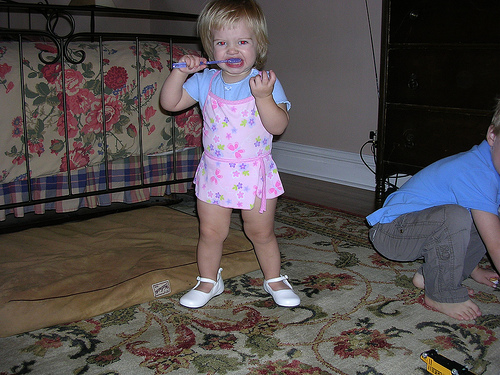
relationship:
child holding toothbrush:
[158, 2, 303, 309] [169, 53, 247, 68]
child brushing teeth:
[158, 2, 303, 309] [226, 58, 242, 66]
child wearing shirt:
[158, 2, 303, 309] [180, 64, 294, 113]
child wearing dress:
[158, 2, 303, 309] [191, 62, 284, 211]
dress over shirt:
[191, 62, 284, 211] [181, 60, 292, 114]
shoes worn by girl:
[148, 258, 409, 367] [156, 0, 323, 309]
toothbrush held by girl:
[172, 58, 243, 69] [156, 0, 323, 309]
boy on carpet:
[361, 100, 498, 323] [1, 183, 498, 373]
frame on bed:
[0, 0, 207, 235] [1, 41, 204, 220]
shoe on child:
[162, 267, 236, 325] [158, 2, 303, 309]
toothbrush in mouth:
[162, 54, 243, 69] [220, 55, 245, 69]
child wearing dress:
[158, 2, 303, 309] [185, 90, 287, 214]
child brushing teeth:
[158, 2, 303, 309] [227, 60, 242, 67]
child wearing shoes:
[158, 2, 303, 309] [160, 270, 324, 325]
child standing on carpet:
[158, 2, 303, 309] [1, 183, 498, 373]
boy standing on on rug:
[361, 100, 498, 323] [2, 177, 497, 373]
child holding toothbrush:
[152, 2, 314, 312] [172, 59, 244, 71]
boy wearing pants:
[361, 100, 498, 323] [367, 204, 486, 302]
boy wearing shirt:
[361, 100, 498, 323] [365, 141, 498, 228]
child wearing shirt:
[158, 2, 303, 309] [180, 67, 292, 109]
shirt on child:
[180, 67, 292, 109] [158, 2, 303, 309]